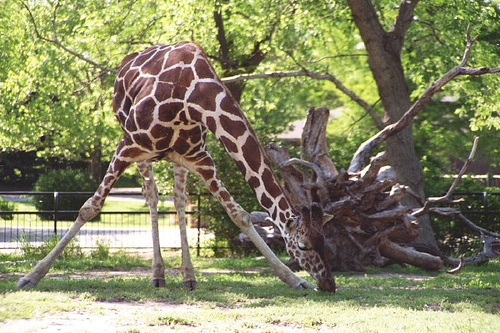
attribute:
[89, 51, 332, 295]
giraffe — tan, brown, tall, bending, white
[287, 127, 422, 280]
trunk — huge, dead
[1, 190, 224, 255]
fence — black, metal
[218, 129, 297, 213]
neck — long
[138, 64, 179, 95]
spot — white, brown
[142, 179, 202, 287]
legs — spraddle, back, white, brown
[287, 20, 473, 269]
tree — medium sized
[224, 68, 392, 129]
branch — brown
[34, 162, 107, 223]
shrub — dark green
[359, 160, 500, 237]
branches — brown, twisted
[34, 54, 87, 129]
leaves — green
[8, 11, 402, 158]
trees — green, large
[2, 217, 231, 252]
road — gray